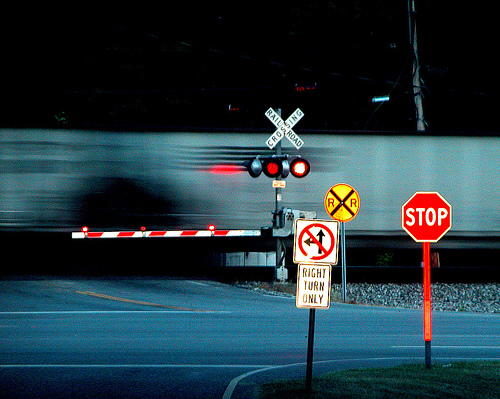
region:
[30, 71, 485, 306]
a move train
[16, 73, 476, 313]
a moving train on a track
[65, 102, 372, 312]
a railroad crossing gaurd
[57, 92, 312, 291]
a railroad crossing light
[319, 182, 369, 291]
a yellow railroad sign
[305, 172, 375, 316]
a sign on a pole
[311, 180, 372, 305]
a yellow sign on a pole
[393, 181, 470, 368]
a red stop sign on a pole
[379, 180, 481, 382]
a stop sign on a pole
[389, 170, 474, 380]
stop sign on a metal pole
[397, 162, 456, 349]
Red and white stop sign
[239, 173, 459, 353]
Traffic signs near edge of road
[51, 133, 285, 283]
Train running the railroad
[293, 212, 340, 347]
White, black and red traffic sign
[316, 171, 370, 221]
Yellow and black traffic sign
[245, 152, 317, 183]
Red traffic lights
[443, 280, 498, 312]
Gray rocks beside railroad tracks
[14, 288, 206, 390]
Paved road with white and yellow lines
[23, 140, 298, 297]
Railroad being used for train crossing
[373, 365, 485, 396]
Grassy area on the side of the road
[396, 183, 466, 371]
A red stop sign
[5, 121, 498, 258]
A train in the background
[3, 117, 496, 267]
Train is blurred due to movement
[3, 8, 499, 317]
Photo was taken at night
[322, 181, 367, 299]
Yellow railroad sign in the background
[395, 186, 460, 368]
Stop sign is on a red pole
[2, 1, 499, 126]
The sky is black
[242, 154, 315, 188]
Railroad crossing light is on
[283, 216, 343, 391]
White signs in the foreground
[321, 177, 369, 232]
Yellow sign is circular shaped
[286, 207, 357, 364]
right turn only street sign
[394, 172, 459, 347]
red and white metal stop sign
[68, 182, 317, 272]
red and white train guard rail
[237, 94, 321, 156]
black and white railroad crossing sign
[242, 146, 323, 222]
red train warning lights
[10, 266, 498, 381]
grey paved street in front of a train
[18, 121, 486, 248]
moving white train cars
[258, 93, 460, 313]
metal street signs in front of a train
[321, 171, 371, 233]
black and yellow railroad crossing sign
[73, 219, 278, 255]
red lights on a red and white guard rail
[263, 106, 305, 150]
A white rail road crossing sign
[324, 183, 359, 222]
a yellow rail road crossing sign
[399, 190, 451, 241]
a red stop sign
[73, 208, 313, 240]
a red and white rail road arm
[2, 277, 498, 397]
the road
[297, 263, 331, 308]
a white and black right turn only sign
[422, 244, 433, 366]
a red pole under the stop sign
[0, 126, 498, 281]
a train on the train tracks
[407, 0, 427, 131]
a pole in the background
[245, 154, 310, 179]
two red train signs